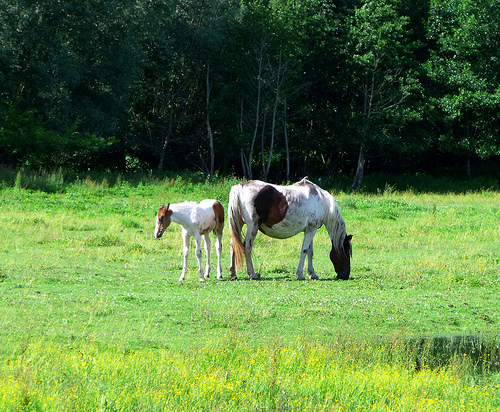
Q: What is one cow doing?
A: Eating grass.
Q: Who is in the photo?
A: No one.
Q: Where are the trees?
A: At the back.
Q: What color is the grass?
A: Green.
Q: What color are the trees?
A: Green.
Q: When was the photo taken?
A: Day time.